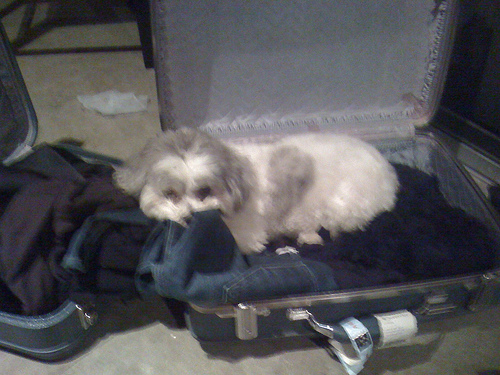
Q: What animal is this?
A: A dog.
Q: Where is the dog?
A: In the suitcase.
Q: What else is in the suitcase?
A: Clothes.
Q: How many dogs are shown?
A: One.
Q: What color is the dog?
A: White.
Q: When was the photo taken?
A: In the evening.